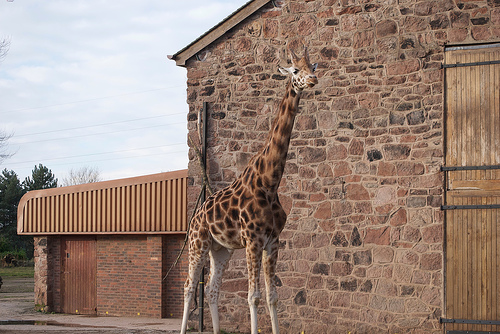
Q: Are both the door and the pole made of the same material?
A: No, the door is made of wood and the pole is made of metal.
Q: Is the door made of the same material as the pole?
A: No, the door is made of wood and the pole is made of metal.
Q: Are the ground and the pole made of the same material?
A: No, the ground is made of concrete and the pole is made of metal.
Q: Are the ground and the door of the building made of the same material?
A: No, the ground is made of concrete and the door is made of wood.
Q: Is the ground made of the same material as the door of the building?
A: No, the ground is made of concrete and the door is made of wood.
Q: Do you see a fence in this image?
A: No, there are no fences.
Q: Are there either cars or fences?
A: No, there are no fences or cars.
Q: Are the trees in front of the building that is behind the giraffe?
A: No, the trees are behind the building.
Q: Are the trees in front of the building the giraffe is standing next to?
A: No, the trees are behind the building.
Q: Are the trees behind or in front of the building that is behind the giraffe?
A: The trees are behind the building.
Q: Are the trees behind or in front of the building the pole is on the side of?
A: The trees are behind the building.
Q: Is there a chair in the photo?
A: No, there are no chairs.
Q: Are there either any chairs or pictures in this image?
A: No, there are no chairs or pictures.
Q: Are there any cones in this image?
A: No, there are no cones.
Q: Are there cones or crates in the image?
A: No, there are no cones or crates.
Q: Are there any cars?
A: No, there are no cars.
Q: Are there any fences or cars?
A: No, there are no cars or fences.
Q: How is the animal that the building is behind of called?
A: The animal is a giraffe.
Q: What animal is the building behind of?
A: The building is behind the giraffe.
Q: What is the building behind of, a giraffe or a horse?
A: The building is behind a giraffe.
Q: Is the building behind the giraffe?
A: Yes, the building is behind the giraffe.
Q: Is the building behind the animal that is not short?
A: Yes, the building is behind the giraffe.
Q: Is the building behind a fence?
A: No, the building is behind the giraffe.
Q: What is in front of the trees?
A: The building is in front of the trees.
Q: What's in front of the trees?
A: The building is in front of the trees.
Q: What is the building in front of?
A: The building is in front of the trees.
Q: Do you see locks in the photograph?
A: No, there are no locks.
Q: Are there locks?
A: No, there are no locks.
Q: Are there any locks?
A: No, there are no locks.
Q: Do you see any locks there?
A: No, there are no locks.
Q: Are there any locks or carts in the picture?
A: No, there are no locks or carts.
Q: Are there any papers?
A: No, there are no papers.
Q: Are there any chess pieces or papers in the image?
A: No, there are no papers or chess pieces.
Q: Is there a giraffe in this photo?
A: Yes, there is a giraffe.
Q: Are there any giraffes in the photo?
A: Yes, there is a giraffe.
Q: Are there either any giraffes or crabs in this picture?
A: Yes, there is a giraffe.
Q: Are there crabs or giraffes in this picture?
A: Yes, there is a giraffe.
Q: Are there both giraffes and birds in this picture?
A: No, there is a giraffe but no birds.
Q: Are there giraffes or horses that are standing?
A: Yes, the giraffe is standing.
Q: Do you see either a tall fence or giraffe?
A: Yes, there is a tall giraffe.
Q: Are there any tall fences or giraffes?
A: Yes, there is a tall giraffe.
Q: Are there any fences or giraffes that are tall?
A: Yes, the giraffe is tall.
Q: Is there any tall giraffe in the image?
A: Yes, there is a tall giraffe.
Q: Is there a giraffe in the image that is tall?
A: Yes, there is a giraffe that is tall.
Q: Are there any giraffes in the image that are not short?
A: Yes, there is a tall giraffe.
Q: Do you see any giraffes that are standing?
A: Yes, there is a giraffe that is standing.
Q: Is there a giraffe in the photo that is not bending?
A: Yes, there is a giraffe that is standing.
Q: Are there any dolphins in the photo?
A: No, there are no dolphins.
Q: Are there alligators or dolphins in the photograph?
A: No, there are no dolphins or alligators.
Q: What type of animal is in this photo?
A: The animal is a giraffe.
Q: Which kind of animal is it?
A: The animal is a giraffe.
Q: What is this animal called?
A: This is a giraffe.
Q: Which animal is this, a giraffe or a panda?
A: This is a giraffe.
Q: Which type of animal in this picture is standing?
A: The animal is a giraffe.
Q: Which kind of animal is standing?
A: The animal is a giraffe.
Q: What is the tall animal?
A: The animal is a giraffe.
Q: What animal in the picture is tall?
A: The animal is a giraffe.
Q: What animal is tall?
A: The animal is a giraffe.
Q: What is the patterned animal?
A: The animal is a giraffe.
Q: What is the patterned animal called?
A: The animal is a giraffe.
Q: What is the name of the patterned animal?
A: The animal is a giraffe.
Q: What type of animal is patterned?
A: The animal is a giraffe.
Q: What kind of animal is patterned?
A: The animal is a giraffe.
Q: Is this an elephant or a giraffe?
A: This is a giraffe.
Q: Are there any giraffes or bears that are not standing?
A: No, there is a giraffe but it is standing.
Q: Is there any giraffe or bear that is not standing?
A: No, there is a giraffe but it is standing.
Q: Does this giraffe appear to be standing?
A: Yes, the giraffe is standing.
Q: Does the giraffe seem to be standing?
A: Yes, the giraffe is standing.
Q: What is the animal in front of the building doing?
A: The giraffe is standing.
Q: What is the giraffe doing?
A: The giraffe is standing.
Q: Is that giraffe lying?
A: No, the giraffe is standing.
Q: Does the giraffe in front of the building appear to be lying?
A: No, the giraffe is standing.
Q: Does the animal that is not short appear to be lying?
A: No, the giraffe is standing.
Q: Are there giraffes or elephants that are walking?
A: No, there is a giraffe but it is standing.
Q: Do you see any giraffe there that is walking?
A: No, there is a giraffe but it is standing.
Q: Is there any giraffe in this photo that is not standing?
A: No, there is a giraffe but it is standing.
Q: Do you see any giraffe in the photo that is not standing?
A: No, there is a giraffe but it is standing.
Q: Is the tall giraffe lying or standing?
A: The giraffe is standing.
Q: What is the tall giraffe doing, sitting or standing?
A: The giraffe is standing.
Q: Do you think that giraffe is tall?
A: Yes, the giraffe is tall.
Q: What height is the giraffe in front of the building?
A: The giraffe is tall.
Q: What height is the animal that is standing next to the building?
A: The giraffe is tall.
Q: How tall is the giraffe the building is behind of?
A: The giraffe is tall.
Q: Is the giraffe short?
A: No, the giraffe is tall.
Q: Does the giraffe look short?
A: No, the giraffe is tall.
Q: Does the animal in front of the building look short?
A: No, the giraffe is tall.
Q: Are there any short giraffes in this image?
A: No, there is a giraffe but it is tall.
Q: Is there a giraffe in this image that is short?
A: No, there is a giraffe but it is tall.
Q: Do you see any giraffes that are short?
A: No, there is a giraffe but it is tall.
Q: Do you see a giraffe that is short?
A: No, there is a giraffe but it is tall.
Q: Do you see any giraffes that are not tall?
A: No, there is a giraffe but it is tall.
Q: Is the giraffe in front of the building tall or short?
A: The giraffe is tall.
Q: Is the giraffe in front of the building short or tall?
A: The giraffe is tall.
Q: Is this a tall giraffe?
A: Yes, this is a tall giraffe.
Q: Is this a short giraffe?
A: No, this is a tall giraffe.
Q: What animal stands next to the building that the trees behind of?
A: The giraffe stands next to the building.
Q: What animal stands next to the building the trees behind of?
A: The giraffe stands next to the building.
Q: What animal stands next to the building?
A: The giraffe stands next to the building.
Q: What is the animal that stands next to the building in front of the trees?
A: The animal is a giraffe.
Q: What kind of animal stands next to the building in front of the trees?
A: The animal is a giraffe.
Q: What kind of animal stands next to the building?
A: The animal is a giraffe.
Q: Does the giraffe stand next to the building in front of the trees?
A: Yes, the giraffe stands next to the building.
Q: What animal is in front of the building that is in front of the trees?
A: The giraffe is in front of the building.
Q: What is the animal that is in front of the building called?
A: The animal is a giraffe.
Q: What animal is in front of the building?
A: The animal is a giraffe.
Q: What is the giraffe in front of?
A: The giraffe is in front of the building.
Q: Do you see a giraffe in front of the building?
A: Yes, there is a giraffe in front of the building.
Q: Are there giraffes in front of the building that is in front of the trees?
A: Yes, there is a giraffe in front of the building.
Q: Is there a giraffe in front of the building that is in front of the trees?
A: Yes, there is a giraffe in front of the building.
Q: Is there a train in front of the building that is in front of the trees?
A: No, there is a giraffe in front of the building.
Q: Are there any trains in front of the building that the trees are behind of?
A: No, there is a giraffe in front of the building.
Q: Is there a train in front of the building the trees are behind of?
A: No, there is a giraffe in front of the building.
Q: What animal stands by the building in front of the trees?
A: The giraffe stands by the building.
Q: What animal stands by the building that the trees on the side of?
A: The giraffe stands by the building.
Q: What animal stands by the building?
A: The giraffe stands by the building.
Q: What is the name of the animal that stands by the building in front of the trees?
A: The animal is a giraffe.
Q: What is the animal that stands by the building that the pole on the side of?
A: The animal is a giraffe.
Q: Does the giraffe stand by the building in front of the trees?
A: Yes, the giraffe stands by the building.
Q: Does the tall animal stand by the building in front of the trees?
A: Yes, the giraffe stands by the building.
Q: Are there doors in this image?
A: Yes, there is a door.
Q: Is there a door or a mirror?
A: Yes, there is a door.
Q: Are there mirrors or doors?
A: Yes, there is a door.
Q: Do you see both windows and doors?
A: No, there is a door but no windows.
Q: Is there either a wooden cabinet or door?
A: Yes, there is a wood door.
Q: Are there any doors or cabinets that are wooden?
A: Yes, the door is wooden.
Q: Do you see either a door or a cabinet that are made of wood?
A: Yes, the door is made of wood.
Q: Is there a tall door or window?
A: Yes, there is a tall door.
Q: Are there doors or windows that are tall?
A: Yes, the door is tall.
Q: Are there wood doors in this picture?
A: Yes, there is a wood door.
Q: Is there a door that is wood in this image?
A: Yes, there is a wood door.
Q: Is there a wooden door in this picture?
A: Yes, there is a wood door.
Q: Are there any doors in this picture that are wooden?
A: Yes, there is a door that is wooden.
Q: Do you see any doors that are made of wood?
A: Yes, there is a door that is made of wood.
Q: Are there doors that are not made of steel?
A: Yes, there is a door that is made of wood.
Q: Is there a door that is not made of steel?
A: Yes, there is a door that is made of wood.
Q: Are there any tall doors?
A: Yes, there is a tall door.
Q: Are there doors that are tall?
A: Yes, there is a door that is tall.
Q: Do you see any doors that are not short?
A: Yes, there is a tall door.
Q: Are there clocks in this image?
A: No, there are no clocks.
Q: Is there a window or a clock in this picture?
A: No, there are no clocks or windows.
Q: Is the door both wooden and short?
A: No, the door is wooden but tall.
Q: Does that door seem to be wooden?
A: Yes, the door is wooden.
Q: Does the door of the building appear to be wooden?
A: Yes, the door is wooden.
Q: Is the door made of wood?
A: Yes, the door is made of wood.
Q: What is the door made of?
A: The door is made of wood.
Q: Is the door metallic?
A: No, the door is wooden.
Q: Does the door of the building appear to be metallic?
A: No, the door is wooden.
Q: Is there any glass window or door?
A: No, there is a door but it is wooden.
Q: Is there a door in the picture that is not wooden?
A: No, there is a door but it is wooden.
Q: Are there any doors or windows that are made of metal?
A: No, there is a door but it is made of wood.